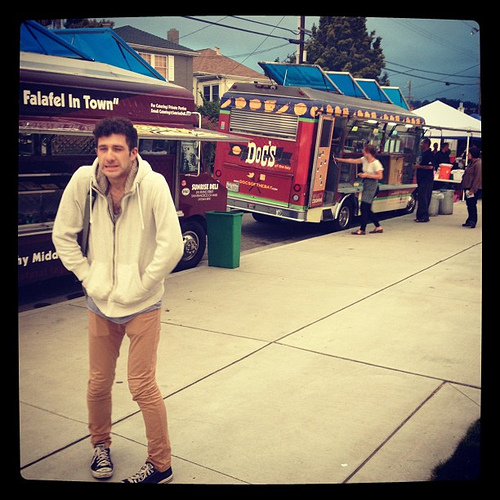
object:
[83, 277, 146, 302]
hands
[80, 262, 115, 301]
coat pockets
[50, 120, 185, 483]
man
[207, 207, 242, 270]
trash can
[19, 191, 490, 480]
sidewalk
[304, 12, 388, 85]
tree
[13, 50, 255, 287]
food vendors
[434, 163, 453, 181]
cooler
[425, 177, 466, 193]
table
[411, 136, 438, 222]
black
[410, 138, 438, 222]
man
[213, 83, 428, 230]
food truck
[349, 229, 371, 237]
flip flops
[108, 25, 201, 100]
house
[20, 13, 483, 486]
background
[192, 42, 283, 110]
house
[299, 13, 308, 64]
telephone pole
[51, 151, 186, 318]
sweatshirt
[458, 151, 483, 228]
woman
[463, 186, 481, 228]
pants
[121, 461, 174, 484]
sneakers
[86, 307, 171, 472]
pants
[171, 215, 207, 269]
truck tire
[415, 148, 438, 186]
shirt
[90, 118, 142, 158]
hair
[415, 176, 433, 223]
pants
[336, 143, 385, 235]
woman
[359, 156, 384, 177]
shirt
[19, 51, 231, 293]
truck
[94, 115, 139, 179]
head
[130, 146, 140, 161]
ear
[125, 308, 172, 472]
leg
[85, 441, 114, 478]
tennis shoe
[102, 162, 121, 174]
mouth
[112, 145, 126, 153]
eye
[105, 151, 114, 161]
nose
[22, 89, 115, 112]
writing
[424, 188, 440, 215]
trash can